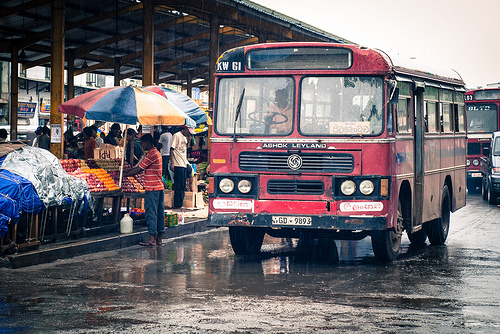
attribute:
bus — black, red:
[195, 35, 471, 269]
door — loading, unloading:
[413, 83, 424, 230]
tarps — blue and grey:
[1, 155, 90, 213]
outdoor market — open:
[1, 3, 376, 262]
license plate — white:
[270, 213, 313, 226]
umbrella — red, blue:
[59, 76, 197, 186]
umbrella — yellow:
[145, 80, 215, 131]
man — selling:
[167, 129, 197, 176]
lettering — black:
[265, 210, 317, 227]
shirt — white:
[168, 127, 192, 172]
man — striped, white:
[115, 113, 224, 264]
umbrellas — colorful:
[57, 73, 184, 138]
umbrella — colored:
[78, 90, 169, 132]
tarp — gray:
[2, 145, 92, 206]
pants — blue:
[145, 189, 165, 239]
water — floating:
[103, 267, 435, 307]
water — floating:
[2, 202, 492, 331]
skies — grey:
[253, 0, 496, 89]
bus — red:
[191, 20, 460, 236]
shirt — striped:
[133, 144, 168, 194]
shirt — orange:
[138, 149, 180, 196]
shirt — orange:
[139, 148, 163, 186]